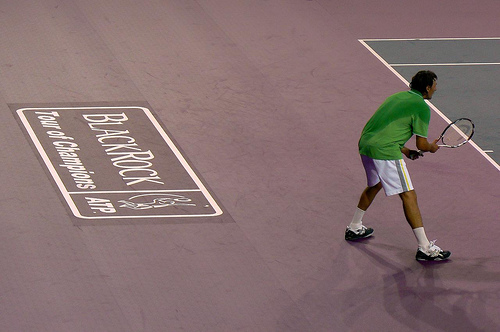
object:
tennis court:
[1, 1, 498, 330]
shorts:
[359, 154, 415, 197]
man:
[344, 70, 474, 263]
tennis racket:
[417, 117, 476, 159]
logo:
[12, 105, 223, 218]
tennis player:
[343, 70, 474, 261]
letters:
[32, 107, 196, 213]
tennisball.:
[25, 17, 497, 330]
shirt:
[358, 90, 431, 160]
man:
[342, 70, 450, 262]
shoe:
[415, 239, 451, 262]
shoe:
[344, 225, 374, 241]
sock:
[412, 226, 431, 254]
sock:
[348, 206, 366, 230]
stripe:
[394, 159, 411, 192]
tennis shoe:
[416, 239, 452, 261]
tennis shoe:
[345, 223, 375, 240]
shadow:
[355, 241, 499, 331]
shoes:
[345, 220, 451, 261]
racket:
[410, 116, 484, 170]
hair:
[407, 69, 437, 101]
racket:
[435, 118, 475, 149]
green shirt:
[358, 90, 431, 161]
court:
[0, 0, 498, 329]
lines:
[358, 37, 500, 173]